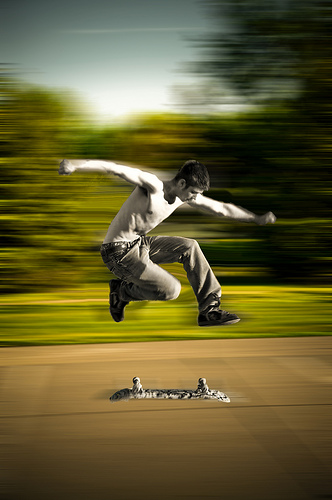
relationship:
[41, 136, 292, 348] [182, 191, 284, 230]
boy has arm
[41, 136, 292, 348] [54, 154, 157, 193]
boy has arm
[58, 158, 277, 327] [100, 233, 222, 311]
boy wearing jeans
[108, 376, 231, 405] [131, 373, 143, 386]
skate has wheels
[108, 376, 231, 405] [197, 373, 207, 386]
skate has wheels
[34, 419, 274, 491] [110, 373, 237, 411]
dirt under skateboard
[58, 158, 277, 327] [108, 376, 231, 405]
boy doing tricks on skate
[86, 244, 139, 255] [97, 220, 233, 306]
belt on jeans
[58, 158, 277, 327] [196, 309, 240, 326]
boy wearing sneaker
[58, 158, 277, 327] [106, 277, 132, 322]
boy wearing sneaker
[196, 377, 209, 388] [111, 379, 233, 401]
wheels under skate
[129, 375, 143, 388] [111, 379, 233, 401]
wheels under skate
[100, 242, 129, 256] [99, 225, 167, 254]
belt on waist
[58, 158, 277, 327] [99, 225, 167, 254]
boy has waist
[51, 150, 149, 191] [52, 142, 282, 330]
arm behind man